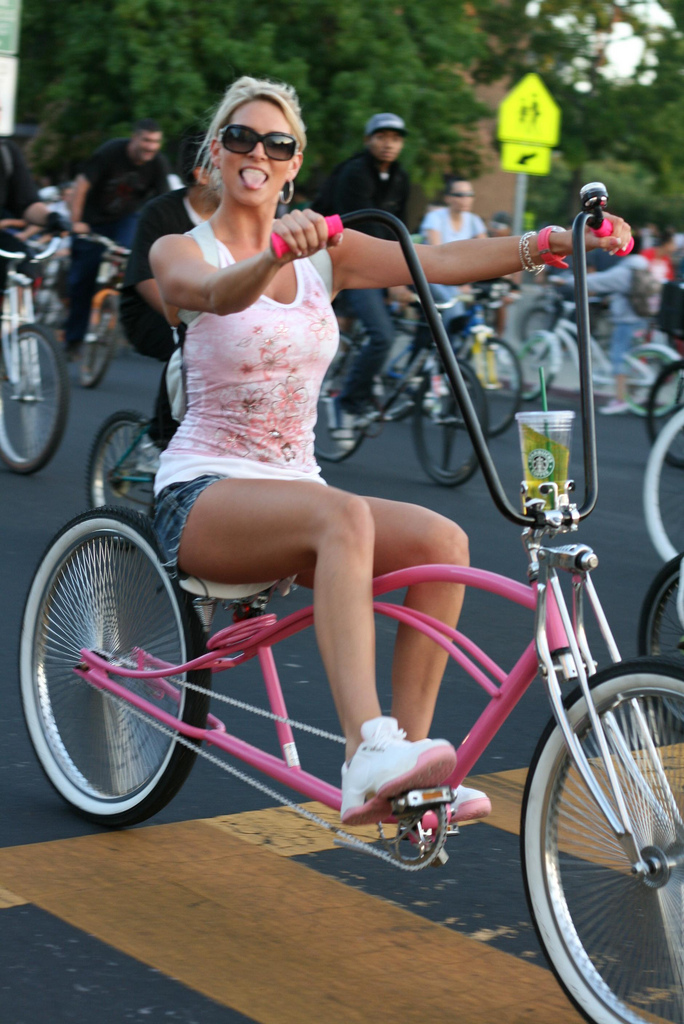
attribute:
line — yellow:
[14, 820, 680, 1022]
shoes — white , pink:
[340, 716, 456, 826]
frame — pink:
[81, 564, 571, 837]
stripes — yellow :
[9, 819, 560, 1022]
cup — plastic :
[508, 413, 570, 511]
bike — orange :
[44, 214, 132, 386]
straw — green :
[536, 367, 555, 471]